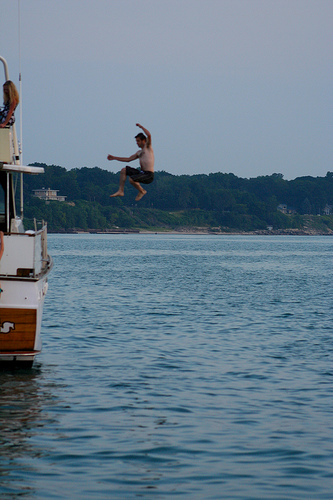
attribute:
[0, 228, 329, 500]
water — ripply, calm, clear, blue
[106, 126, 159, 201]
person — jumping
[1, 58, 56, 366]
boat — red, white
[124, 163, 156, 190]
pants — black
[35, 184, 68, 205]
home — multilevel, 2 story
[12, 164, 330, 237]
trees — green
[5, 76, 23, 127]
woman — blonde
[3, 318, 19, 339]
s — white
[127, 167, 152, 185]
shorts — black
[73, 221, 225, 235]
beach — sandy, brown